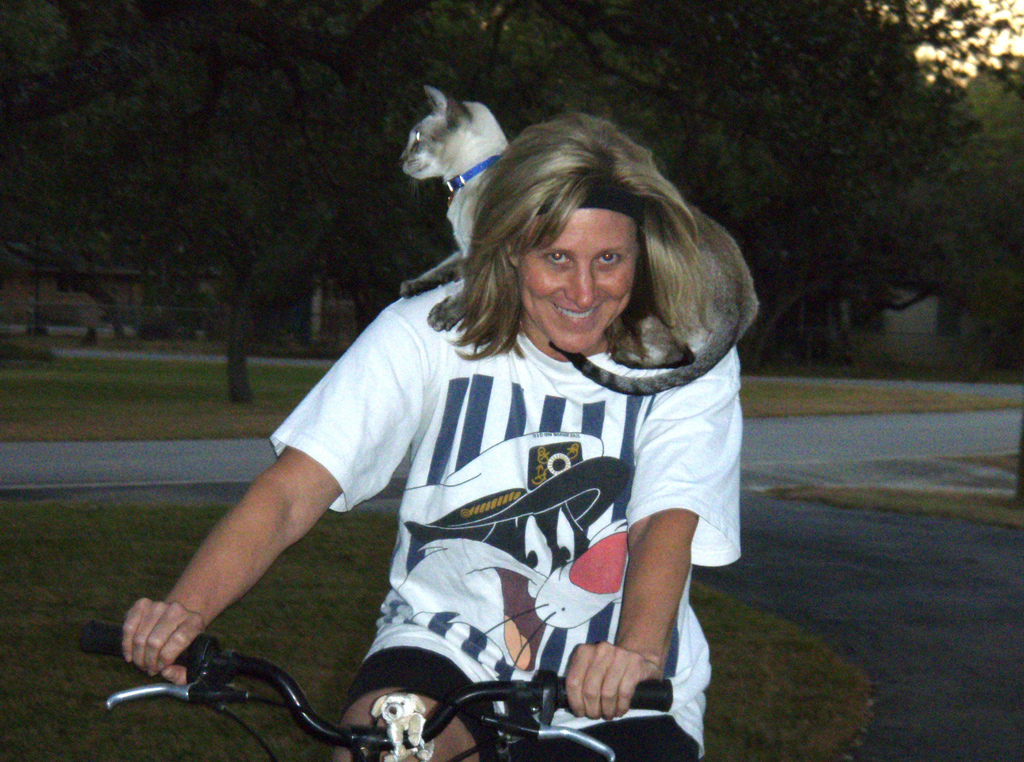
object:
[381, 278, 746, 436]
girl's shoulders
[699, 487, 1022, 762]
street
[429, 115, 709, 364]
head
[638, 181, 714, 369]
hair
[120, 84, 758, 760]
lady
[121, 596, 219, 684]
hands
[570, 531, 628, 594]
nose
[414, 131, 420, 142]
eye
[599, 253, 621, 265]
eye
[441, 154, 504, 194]
collar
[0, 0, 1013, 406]
tree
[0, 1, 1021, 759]
city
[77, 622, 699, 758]
bike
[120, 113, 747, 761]
lady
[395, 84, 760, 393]
cat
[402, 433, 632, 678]
cartoon cat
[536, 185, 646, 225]
headband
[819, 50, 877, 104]
leaves